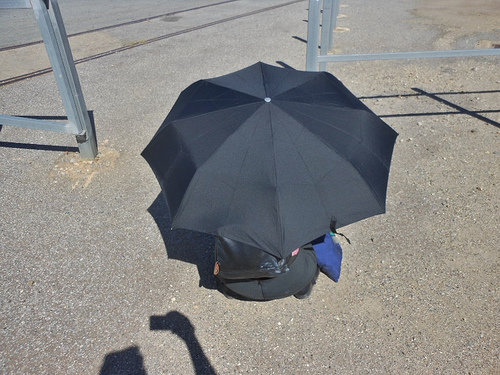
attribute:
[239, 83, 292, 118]
tip — white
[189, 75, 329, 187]
umbrella — black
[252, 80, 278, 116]
button — metal